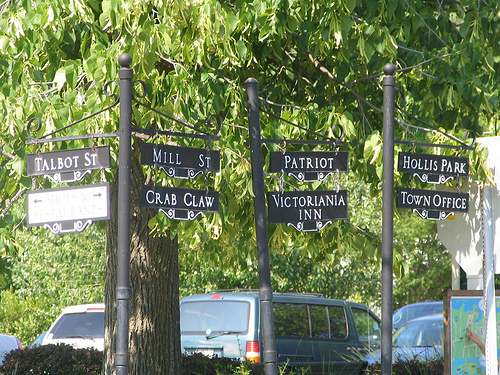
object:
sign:
[24, 143, 113, 182]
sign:
[140, 143, 223, 181]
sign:
[136, 185, 223, 221]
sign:
[267, 151, 351, 184]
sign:
[265, 189, 348, 233]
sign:
[397, 151, 469, 184]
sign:
[395, 186, 470, 221]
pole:
[113, 53, 133, 375]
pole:
[244, 77, 279, 375]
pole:
[381, 62, 399, 374]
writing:
[32, 152, 100, 173]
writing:
[150, 148, 213, 169]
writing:
[143, 189, 216, 207]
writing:
[284, 154, 334, 171]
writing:
[270, 193, 346, 222]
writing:
[402, 155, 468, 174]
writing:
[400, 189, 468, 209]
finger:
[465, 327, 476, 335]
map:
[442, 290, 499, 374]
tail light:
[245, 339, 261, 362]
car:
[179, 288, 397, 374]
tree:
[0, 0, 499, 372]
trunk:
[100, 120, 184, 374]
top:
[118, 52, 129, 68]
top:
[242, 76, 260, 87]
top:
[381, 62, 397, 76]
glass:
[180, 299, 252, 334]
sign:
[24, 181, 111, 235]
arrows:
[92, 192, 103, 198]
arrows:
[33, 198, 43, 204]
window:
[49, 312, 106, 340]